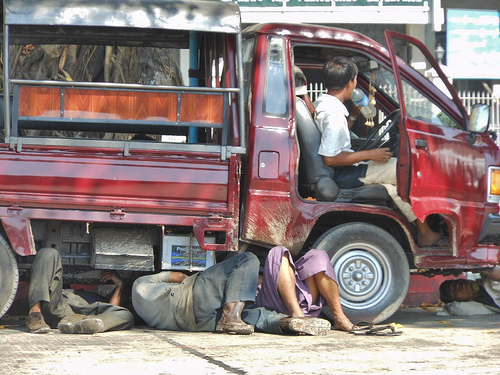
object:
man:
[313, 59, 457, 248]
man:
[259, 244, 364, 333]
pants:
[251, 245, 338, 318]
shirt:
[132, 271, 208, 331]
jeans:
[193, 251, 290, 335]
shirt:
[312, 92, 358, 166]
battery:
[161, 234, 217, 271]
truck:
[0, 0, 499, 327]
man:
[439, 268, 499, 316]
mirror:
[466, 103, 490, 134]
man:
[24, 247, 135, 333]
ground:
[0, 307, 499, 374]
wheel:
[309, 222, 410, 330]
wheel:
[0, 222, 20, 321]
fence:
[306, 78, 499, 142]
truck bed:
[0, 2, 241, 154]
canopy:
[0, 0, 246, 161]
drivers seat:
[293, 62, 403, 203]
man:
[131, 250, 332, 337]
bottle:
[351, 89, 377, 119]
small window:
[264, 33, 289, 118]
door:
[384, 29, 487, 257]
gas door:
[257, 151, 280, 179]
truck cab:
[239, 23, 499, 270]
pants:
[353, 158, 418, 222]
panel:
[12, 76, 234, 128]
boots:
[216, 302, 254, 335]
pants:
[27, 246, 131, 331]